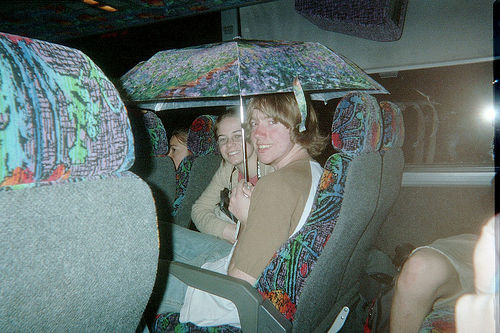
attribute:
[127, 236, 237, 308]
jeans — blue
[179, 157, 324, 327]
short sleeve — tan, white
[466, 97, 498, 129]
light — glare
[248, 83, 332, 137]
hair — blonde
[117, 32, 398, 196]
umbrella — open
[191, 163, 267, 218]
sweater — tan, long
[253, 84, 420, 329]
gray/colorful seats — grey, patterned, colorful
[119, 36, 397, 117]
umbrella — floral, print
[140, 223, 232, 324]
jeans — light wash